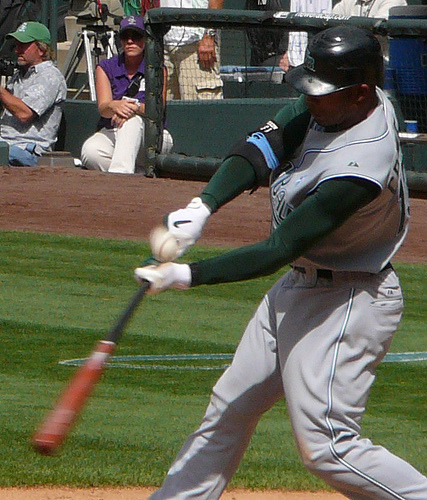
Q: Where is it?
A: This is at the field.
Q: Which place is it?
A: It is a field.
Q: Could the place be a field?
A: Yes, it is a field.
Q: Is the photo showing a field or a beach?
A: It is showing a field.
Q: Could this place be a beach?
A: No, it is a field.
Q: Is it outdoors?
A: Yes, it is outdoors.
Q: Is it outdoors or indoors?
A: It is outdoors.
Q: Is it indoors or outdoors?
A: It is outdoors.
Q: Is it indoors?
A: No, it is outdoors.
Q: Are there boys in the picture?
A: No, there are no boys.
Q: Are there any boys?
A: No, there are no boys.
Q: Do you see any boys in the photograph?
A: No, there are no boys.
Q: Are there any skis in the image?
A: No, there are no skis.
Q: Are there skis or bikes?
A: No, there are no skis or bikes.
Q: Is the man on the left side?
A: Yes, the man is on the left of the image.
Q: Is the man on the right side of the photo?
A: No, the man is on the left of the image.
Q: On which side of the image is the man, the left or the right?
A: The man is on the left of the image.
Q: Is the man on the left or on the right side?
A: The man is on the left of the image.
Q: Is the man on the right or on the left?
A: The man is on the left of the image.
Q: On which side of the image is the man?
A: The man is on the left of the image.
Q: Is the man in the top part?
A: Yes, the man is in the top of the image.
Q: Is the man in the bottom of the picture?
A: No, the man is in the top of the image.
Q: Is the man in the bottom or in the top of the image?
A: The man is in the top of the image.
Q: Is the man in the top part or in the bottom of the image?
A: The man is in the top of the image.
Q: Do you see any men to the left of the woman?
A: Yes, there is a man to the left of the woman.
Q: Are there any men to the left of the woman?
A: Yes, there is a man to the left of the woman.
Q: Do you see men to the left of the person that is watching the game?
A: Yes, there is a man to the left of the woman.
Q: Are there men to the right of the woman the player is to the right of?
A: No, the man is to the left of the woman.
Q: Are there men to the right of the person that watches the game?
A: No, the man is to the left of the woman.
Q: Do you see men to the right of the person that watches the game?
A: No, the man is to the left of the woman.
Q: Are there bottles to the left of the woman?
A: No, there is a man to the left of the woman.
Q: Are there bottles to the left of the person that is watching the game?
A: No, there is a man to the left of the woman.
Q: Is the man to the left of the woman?
A: Yes, the man is to the left of the woman.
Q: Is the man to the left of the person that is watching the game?
A: Yes, the man is to the left of the woman.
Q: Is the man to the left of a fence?
A: No, the man is to the left of the woman.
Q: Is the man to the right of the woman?
A: No, the man is to the left of the woman.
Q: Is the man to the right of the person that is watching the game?
A: No, the man is to the left of the woman.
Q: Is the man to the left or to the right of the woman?
A: The man is to the left of the woman.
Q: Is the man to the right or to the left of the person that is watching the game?
A: The man is to the left of the woman.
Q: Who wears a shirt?
A: The man wears a shirt.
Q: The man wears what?
A: The man wears a shirt.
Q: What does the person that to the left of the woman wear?
A: The man wears a shirt.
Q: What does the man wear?
A: The man wears a shirt.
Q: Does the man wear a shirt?
A: Yes, the man wears a shirt.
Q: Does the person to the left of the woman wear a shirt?
A: Yes, the man wears a shirt.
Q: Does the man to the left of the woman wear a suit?
A: No, the man wears a shirt.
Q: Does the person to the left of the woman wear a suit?
A: No, the man wears a shirt.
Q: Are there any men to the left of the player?
A: Yes, there is a man to the left of the player.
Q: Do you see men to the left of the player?
A: Yes, there is a man to the left of the player.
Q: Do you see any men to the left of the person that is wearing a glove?
A: Yes, there is a man to the left of the player.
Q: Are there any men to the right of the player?
A: No, the man is to the left of the player.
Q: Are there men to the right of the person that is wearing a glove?
A: No, the man is to the left of the player.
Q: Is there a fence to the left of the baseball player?
A: No, there is a man to the left of the player.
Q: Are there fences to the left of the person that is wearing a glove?
A: No, there is a man to the left of the player.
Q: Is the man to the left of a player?
A: Yes, the man is to the left of a player.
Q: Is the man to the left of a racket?
A: No, the man is to the left of a player.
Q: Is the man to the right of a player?
A: No, the man is to the left of a player.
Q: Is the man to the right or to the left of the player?
A: The man is to the left of the player.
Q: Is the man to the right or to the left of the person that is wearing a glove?
A: The man is to the left of the player.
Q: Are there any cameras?
A: Yes, there is a camera.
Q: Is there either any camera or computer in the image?
A: Yes, there is a camera.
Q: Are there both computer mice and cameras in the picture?
A: No, there is a camera but no computer mice.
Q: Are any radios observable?
A: No, there are no radios.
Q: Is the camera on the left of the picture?
A: Yes, the camera is on the left of the image.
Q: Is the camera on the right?
A: No, the camera is on the left of the image.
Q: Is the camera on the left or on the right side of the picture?
A: The camera is on the left of the image.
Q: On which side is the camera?
A: The camera is on the left of the image.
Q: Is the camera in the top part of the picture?
A: Yes, the camera is in the top of the image.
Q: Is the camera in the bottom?
A: No, the camera is in the top of the image.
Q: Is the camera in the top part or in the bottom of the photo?
A: The camera is in the top of the image.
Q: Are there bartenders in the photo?
A: No, there are no bartenders.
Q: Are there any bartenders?
A: No, there are no bartenders.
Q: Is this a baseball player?
A: Yes, this is a baseball player.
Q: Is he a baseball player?
A: Yes, this is a baseball player.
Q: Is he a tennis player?
A: No, this is a baseball player.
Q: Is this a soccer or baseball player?
A: This is a baseball player.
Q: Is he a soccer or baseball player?
A: This is a baseball player.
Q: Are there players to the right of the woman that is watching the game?
A: Yes, there is a player to the right of the woman.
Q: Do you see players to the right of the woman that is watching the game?
A: Yes, there is a player to the right of the woman.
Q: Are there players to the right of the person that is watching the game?
A: Yes, there is a player to the right of the woman.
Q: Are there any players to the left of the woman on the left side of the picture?
A: No, the player is to the right of the woman.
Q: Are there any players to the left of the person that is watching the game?
A: No, the player is to the right of the woman.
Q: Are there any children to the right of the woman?
A: No, there is a player to the right of the woman.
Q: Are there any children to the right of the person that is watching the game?
A: No, there is a player to the right of the woman.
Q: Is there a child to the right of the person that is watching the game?
A: No, there is a player to the right of the woman.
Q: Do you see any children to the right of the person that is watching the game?
A: No, there is a player to the right of the woman.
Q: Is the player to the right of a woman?
A: Yes, the player is to the right of a woman.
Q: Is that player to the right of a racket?
A: No, the player is to the right of a woman.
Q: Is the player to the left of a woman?
A: No, the player is to the right of a woman.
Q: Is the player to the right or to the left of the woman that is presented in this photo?
A: The player is to the right of the woman.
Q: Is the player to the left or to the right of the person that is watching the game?
A: The player is to the right of the woman.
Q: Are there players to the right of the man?
A: Yes, there is a player to the right of the man.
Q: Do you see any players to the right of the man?
A: Yes, there is a player to the right of the man.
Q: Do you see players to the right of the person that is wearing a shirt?
A: Yes, there is a player to the right of the man.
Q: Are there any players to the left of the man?
A: No, the player is to the right of the man.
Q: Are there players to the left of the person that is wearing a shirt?
A: No, the player is to the right of the man.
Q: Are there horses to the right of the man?
A: No, there is a player to the right of the man.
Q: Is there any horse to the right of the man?
A: No, there is a player to the right of the man.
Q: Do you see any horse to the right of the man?
A: No, there is a player to the right of the man.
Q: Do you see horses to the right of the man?
A: No, there is a player to the right of the man.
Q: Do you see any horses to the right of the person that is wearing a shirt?
A: No, there is a player to the right of the man.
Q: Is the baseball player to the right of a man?
A: Yes, the player is to the right of a man.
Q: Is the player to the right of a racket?
A: No, the player is to the right of a man.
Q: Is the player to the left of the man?
A: No, the player is to the right of the man.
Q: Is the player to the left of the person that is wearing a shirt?
A: No, the player is to the right of the man.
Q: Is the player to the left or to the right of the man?
A: The player is to the right of the man.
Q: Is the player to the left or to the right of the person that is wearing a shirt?
A: The player is to the right of the man.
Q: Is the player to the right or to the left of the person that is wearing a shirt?
A: The player is to the right of the man.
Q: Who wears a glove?
A: The player wears a glove.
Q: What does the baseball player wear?
A: The player wears a glove.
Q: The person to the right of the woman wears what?
A: The player wears a glove.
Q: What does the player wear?
A: The player wears a glove.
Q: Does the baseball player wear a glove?
A: Yes, the player wears a glove.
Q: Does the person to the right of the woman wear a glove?
A: Yes, the player wears a glove.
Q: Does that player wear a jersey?
A: No, the player wears a glove.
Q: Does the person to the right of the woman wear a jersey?
A: No, the player wears a glove.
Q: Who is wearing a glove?
A: The player is wearing a glove.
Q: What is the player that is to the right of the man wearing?
A: The player is wearing a glove.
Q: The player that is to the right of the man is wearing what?
A: The player is wearing a glove.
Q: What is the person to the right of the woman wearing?
A: The player is wearing a glove.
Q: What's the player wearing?
A: The player is wearing a glove.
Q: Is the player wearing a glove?
A: Yes, the player is wearing a glove.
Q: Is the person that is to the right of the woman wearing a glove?
A: Yes, the player is wearing a glove.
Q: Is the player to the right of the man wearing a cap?
A: No, the player is wearing a glove.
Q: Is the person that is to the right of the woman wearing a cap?
A: No, the player is wearing a glove.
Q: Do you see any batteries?
A: No, there are no batteries.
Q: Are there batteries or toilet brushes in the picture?
A: No, there are no batteries or toilet brushes.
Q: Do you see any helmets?
A: Yes, there is a helmet.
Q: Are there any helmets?
A: Yes, there is a helmet.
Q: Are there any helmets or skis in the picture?
A: Yes, there is a helmet.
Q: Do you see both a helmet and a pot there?
A: No, there is a helmet but no pots.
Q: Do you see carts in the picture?
A: No, there are no carts.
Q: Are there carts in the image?
A: No, there are no carts.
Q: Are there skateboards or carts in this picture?
A: No, there are no carts or skateboards.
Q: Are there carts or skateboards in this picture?
A: No, there are no carts or skateboards.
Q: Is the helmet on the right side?
A: Yes, the helmet is on the right of the image.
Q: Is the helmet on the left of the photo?
A: No, the helmet is on the right of the image.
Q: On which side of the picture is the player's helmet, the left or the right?
A: The helmet is on the right of the image.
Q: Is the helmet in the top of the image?
A: Yes, the helmet is in the top of the image.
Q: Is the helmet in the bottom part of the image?
A: No, the helmet is in the top of the image.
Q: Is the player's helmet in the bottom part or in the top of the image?
A: The helmet is in the top of the image.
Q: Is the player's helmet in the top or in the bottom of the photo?
A: The helmet is in the top of the image.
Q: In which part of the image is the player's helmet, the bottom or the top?
A: The helmet is in the top of the image.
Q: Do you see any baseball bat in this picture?
A: Yes, there is a baseball bat.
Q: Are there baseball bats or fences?
A: Yes, there is a baseball bat.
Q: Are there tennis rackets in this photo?
A: No, there are no tennis rackets.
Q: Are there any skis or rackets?
A: No, there are no rackets or skis.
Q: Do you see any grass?
A: Yes, there is grass.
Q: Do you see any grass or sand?
A: Yes, there is grass.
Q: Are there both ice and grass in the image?
A: No, there is grass but no ice.